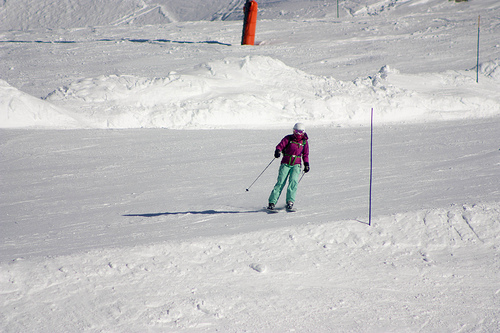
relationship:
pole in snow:
[367, 102, 376, 224] [0, 1, 496, 330]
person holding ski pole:
[262, 120, 313, 215] [241, 150, 281, 195]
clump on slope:
[7, 250, 24, 262] [0, 219, 492, 329]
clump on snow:
[1, 55, 498, 129] [0, 1, 496, 330]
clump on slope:
[377, 62, 401, 76] [3, 1, 498, 331]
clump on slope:
[105, 260, 118, 272] [6, 197, 499, 328]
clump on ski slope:
[247, 259, 274, 273] [1, 0, 495, 331]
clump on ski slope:
[105, 260, 118, 272] [1, 0, 495, 331]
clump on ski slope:
[215, 241, 224, 251] [1, 0, 495, 331]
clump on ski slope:
[205, 65, 335, 114] [1, 0, 495, 331]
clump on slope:
[391, 192, 491, 258] [13, 32, 497, 326]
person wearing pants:
[262, 120, 313, 215] [267, 159, 304, 213]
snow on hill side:
[150, 287, 237, 327] [50, 21, 497, 317]